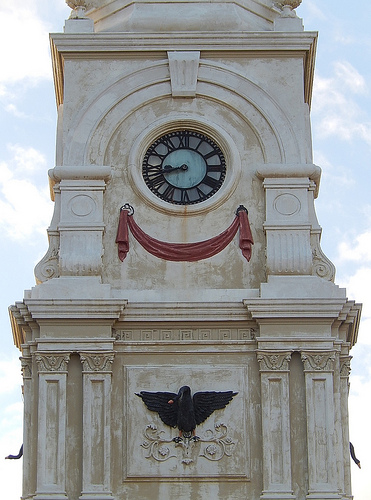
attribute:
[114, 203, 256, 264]
banner — stone, painted, red, long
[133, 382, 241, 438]
swan — stone, black, a bird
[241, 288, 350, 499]
pillar — decorative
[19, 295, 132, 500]
pillar — decorative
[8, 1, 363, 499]
tower — beige, grayish brown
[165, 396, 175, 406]
beak — orange, long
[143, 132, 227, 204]
face — brown, gray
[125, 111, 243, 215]
clock — round, black, white, large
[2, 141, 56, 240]
clouds — white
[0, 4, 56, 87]
clouds — white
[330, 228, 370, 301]
clouds — white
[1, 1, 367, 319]
sky — blue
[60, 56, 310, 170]
arch — decorative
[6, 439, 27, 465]
item — black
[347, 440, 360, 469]
item — black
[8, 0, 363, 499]
monument — tall, white, beige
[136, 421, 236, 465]
leaves — decorative, spiraling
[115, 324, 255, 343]
boxes — decorative, small, spiraling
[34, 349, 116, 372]
design — intricate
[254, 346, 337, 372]
design — intricate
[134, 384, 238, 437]
bird — black, a statue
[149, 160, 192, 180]
hands — black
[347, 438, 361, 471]
bird — on the right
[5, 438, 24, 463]
bird — on the left, a statue